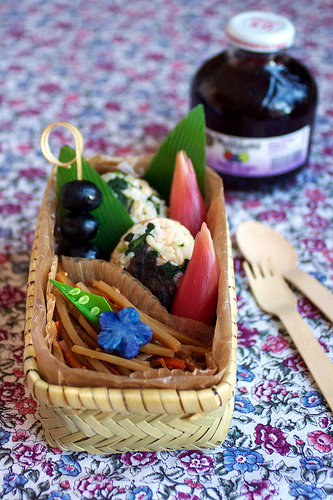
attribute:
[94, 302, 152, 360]
flower — blue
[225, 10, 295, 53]
lid — white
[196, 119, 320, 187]
label — white and purple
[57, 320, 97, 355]
sticks — brown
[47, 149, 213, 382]
wax paper — brown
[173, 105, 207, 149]
leaf — green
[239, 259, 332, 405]
fork — plastic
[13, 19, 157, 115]
flowered pattern — purple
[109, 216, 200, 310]
ball — rice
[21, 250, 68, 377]
basket — wicker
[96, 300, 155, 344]
flower — blue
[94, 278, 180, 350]
vegetable — pickled, sliced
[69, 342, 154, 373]
vegetable — pickled, sliced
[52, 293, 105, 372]
vegetable — pickled, sliced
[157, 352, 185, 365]
vegetable — pickled, sliced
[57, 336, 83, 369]
vegetable — pickled, sliced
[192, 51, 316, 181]
drink — vitamin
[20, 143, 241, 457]
basket — wicker